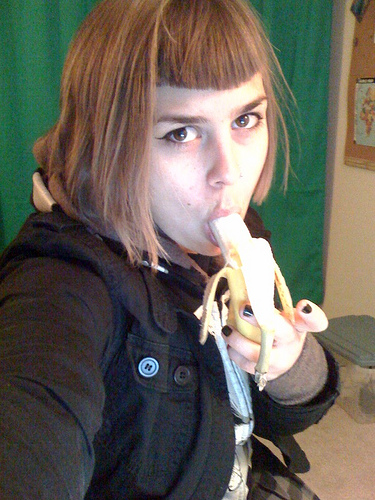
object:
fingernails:
[243, 303, 255, 317]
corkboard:
[341, 0, 375, 173]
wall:
[318, 0, 375, 321]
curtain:
[0, 0, 333, 313]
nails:
[301, 303, 312, 316]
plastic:
[307, 314, 375, 427]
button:
[173, 363, 192, 387]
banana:
[196, 212, 296, 391]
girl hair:
[56, 0, 301, 278]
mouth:
[205, 208, 245, 249]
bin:
[311, 313, 375, 425]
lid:
[310, 313, 375, 371]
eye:
[156, 125, 203, 145]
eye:
[230, 112, 262, 131]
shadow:
[304, 347, 337, 411]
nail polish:
[301, 303, 313, 314]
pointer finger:
[279, 297, 329, 336]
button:
[137, 353, 162, 380]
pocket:
[99, 334, 201, 494]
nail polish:
[221, 325, 232, 338]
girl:
[0, 0, 343, 500]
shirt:
[29, 166, 257, 500]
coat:
[0, 205, 343, 500]